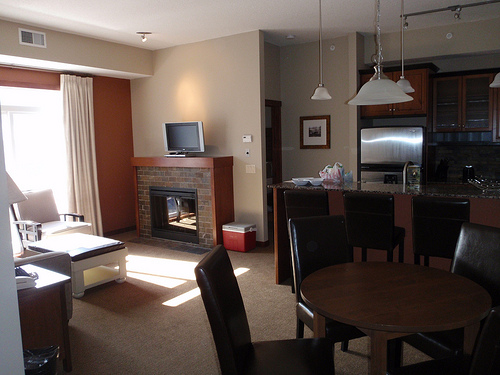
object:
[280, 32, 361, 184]
wall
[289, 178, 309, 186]
bowls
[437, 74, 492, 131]
cabinet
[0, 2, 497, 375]
kitchen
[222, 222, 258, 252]
cooler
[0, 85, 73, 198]
window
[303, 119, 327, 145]
picture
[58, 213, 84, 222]
arm rest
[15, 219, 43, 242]
arm rest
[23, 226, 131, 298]
coffee table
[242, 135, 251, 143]
thermostat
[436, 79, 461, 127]
glass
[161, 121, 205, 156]
television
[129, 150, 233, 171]
mantel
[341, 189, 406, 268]
chair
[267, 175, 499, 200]
counter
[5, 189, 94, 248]
chair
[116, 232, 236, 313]
sunlight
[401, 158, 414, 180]
faucet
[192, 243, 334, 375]
chair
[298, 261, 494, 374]
table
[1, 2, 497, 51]
ceiling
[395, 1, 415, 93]
light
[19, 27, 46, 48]
vent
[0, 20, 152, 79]
wall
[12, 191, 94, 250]
frame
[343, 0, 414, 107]
light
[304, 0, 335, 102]
light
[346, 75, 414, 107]
cover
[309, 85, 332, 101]
cover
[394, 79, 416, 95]
cover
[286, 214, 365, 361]
chair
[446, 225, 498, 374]
chair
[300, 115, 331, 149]
frame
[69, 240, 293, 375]
floor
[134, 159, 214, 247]
fireplace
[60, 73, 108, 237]
curtains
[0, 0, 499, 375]
house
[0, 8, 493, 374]
room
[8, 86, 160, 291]
natural light